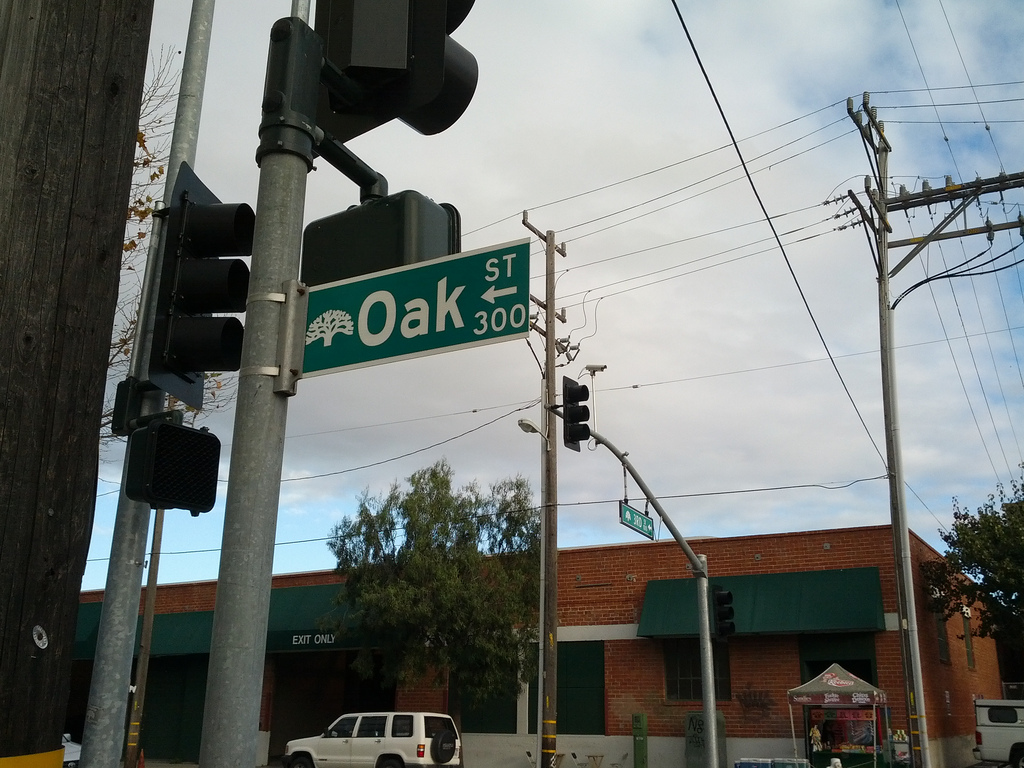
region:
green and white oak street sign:
[251, 230, 540, 407]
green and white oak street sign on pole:
[230, 229, 537, 540]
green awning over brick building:
[642, 565, 892, 709]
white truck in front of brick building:
[286, 699, 463, 761]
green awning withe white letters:
[270, 580, 401, 660]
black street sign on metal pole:
[552, 383, 724, 764]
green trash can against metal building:
[674, 706, 725, 764]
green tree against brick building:
[314, 463, 556, 759]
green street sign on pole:
[297, 247, 538, 374]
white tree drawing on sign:
[302, 300, 361, 355]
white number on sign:
[473, 300, 538, 333]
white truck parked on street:
[286, 707, 463, 766]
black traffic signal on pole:
[700, 584, 755, 649]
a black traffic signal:
[122, 133, 266, 387]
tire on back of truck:
[425, 720, 461, 766]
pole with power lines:
[514, 215, 579, 765]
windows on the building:
[654, 636, 741, 701]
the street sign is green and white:
[302, 237, 530, 383]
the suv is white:
[282, 707, 460, 766]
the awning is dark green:
[634, 568, 884, 639]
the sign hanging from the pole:
[196, 0, 533, 766]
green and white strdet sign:
[263, 247, 520, 369]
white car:
[283, 692, 440, 762]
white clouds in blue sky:
[512, 40, 585, 86]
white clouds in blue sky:
[678, 367, 759, 440]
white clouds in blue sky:
[646, 230, 906, 443]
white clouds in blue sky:
[371, 388, 458, 440]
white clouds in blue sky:
[728, 25, 806, 89]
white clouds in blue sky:
[567, 110, 625, 159]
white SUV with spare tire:
[282, 688, 497, 762]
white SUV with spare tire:
[270, 692, 473, 766]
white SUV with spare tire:
[275, 688, 473, 766]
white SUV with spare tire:
[279, 689, 470, 763]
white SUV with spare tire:
[275, 689, 469, 757]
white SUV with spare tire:
[282, 696, 461, 753]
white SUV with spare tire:
[275, 696, 485, 766]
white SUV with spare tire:
[275, 695, 485, 762]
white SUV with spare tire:
[279, 699, 485, 758]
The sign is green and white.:
[264, 262, 568, 362]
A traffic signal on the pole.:
[152, 148, 241, 406]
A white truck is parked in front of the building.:
[299, 701, 481, 766]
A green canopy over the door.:
[634, 554, 895, 649]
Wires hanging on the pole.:
[558, 82, 1023, 321]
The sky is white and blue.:
[325, 37, 943, 445]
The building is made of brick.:
[527, 516, 1012, 733]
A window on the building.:
[645, 616, 748, 709]